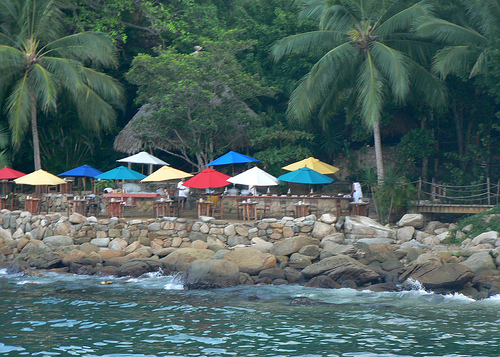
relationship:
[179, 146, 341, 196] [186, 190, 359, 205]
umbrellas at table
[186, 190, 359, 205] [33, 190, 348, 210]
table behind tables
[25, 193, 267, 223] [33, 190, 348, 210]
chairs around tables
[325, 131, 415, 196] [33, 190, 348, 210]
hut behind tables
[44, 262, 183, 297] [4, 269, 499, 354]
waves of ocean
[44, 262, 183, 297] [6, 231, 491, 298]
waves on rocks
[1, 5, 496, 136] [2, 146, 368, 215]
palms over restaurant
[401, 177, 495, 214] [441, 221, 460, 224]
bridge crossing stream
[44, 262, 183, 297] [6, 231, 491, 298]
waves into rocks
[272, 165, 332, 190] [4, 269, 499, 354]
umbrella near ocean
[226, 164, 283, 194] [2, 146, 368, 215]
umbrella at restaurant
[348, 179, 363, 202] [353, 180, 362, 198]
person in uniform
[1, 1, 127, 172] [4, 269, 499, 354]
palm tree near ocean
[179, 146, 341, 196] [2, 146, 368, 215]
umbrellas at restaurant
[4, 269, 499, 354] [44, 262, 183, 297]
ocean has waves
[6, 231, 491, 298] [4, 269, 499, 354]
rocks near ocean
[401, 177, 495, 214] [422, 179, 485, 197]
bridge has ropes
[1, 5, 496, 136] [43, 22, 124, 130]
palms have leaves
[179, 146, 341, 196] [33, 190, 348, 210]
umbrellas and tables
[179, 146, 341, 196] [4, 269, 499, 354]
umbrellas near ocean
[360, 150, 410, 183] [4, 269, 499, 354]
wall by ocean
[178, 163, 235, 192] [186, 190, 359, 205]
umbrella over table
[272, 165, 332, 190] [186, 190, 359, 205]
umbrella over table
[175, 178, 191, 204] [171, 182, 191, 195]
person wearing shirt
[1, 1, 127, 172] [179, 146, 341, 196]
palm tree behind umbrellas